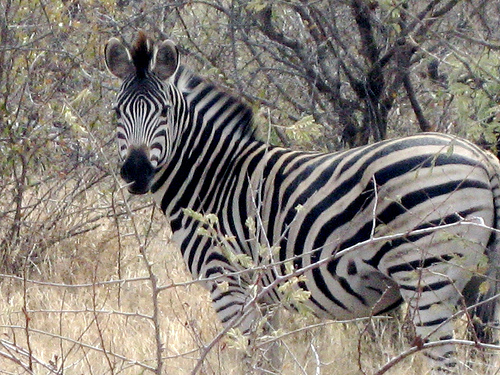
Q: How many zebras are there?
A: 1.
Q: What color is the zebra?
A: Black and white.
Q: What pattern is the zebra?
A: Striped.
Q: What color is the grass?
A: Brown.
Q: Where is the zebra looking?
A: At the camera.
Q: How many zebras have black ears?
A: One.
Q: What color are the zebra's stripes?
A: Black and white.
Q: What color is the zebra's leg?
A: Black and white.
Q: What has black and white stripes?
A: An animal.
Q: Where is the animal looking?
A: Toward the front.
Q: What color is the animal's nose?
A: Black.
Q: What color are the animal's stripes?
A: Black.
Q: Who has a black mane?
A: A zebra.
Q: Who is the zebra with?
A: By itself.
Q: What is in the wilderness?
A: Zebra.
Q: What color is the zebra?
A: Black and white.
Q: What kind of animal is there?
A: Zebra.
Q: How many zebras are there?
A: One.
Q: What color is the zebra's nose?
A: Black.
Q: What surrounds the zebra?
A: Tree branches.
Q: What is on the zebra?
A: Stripes.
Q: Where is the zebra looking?
A: At the camera.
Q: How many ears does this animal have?
A: Two.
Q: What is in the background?
A: Trees.